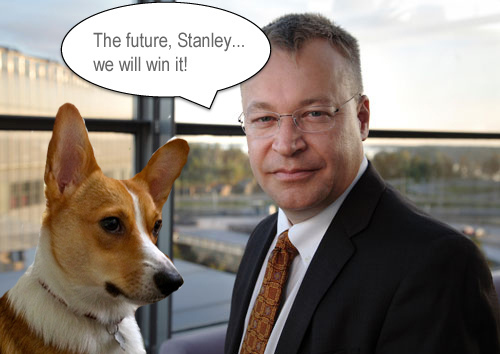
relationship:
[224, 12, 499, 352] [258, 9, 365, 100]
man has hair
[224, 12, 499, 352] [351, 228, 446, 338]
man wearing suit jacket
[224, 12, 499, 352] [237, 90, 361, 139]
man wearing glasses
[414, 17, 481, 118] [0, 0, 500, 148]
clouds in sky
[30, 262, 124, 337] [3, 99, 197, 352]
neck on dog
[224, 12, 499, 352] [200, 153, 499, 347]
man wears suit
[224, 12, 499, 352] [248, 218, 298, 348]
man wears tie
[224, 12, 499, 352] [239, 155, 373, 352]
man wears white shirt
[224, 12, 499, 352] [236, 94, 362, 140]
man wears glasses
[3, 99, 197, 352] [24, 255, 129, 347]
dog wearing collar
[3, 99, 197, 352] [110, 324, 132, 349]
dog wearing tags